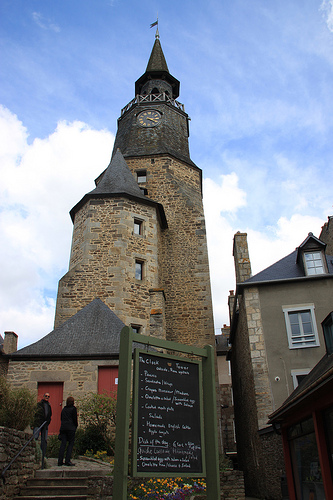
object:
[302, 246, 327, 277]
window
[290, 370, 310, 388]
window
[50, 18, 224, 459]
clock tower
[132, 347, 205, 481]
frame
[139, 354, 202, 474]
blackboard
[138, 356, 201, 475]
menu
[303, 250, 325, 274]
window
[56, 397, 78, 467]
man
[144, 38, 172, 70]
roof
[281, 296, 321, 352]
window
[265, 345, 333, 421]
roof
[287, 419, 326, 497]
window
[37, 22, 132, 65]
blue sky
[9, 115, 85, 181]
clouds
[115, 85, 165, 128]
wall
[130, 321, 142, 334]
window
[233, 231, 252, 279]
chimney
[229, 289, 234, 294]
chimney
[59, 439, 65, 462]
legs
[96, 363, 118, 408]
door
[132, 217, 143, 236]
window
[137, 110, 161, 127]
clock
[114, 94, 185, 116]
terrace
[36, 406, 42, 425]
arm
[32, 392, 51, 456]
man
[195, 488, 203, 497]
flowers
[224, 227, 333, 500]
house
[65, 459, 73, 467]
feet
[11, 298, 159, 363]
roof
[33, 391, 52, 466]
man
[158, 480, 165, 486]
flower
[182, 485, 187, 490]
flower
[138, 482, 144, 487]
flower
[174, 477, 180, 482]
flower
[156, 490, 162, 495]
flower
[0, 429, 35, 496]
wall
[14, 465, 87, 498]
steps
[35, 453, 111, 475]
landing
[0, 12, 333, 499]
building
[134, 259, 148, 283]
window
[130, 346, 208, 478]
sign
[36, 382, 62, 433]
door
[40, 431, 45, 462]
leg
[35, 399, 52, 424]
shirt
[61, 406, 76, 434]
back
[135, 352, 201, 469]
writing